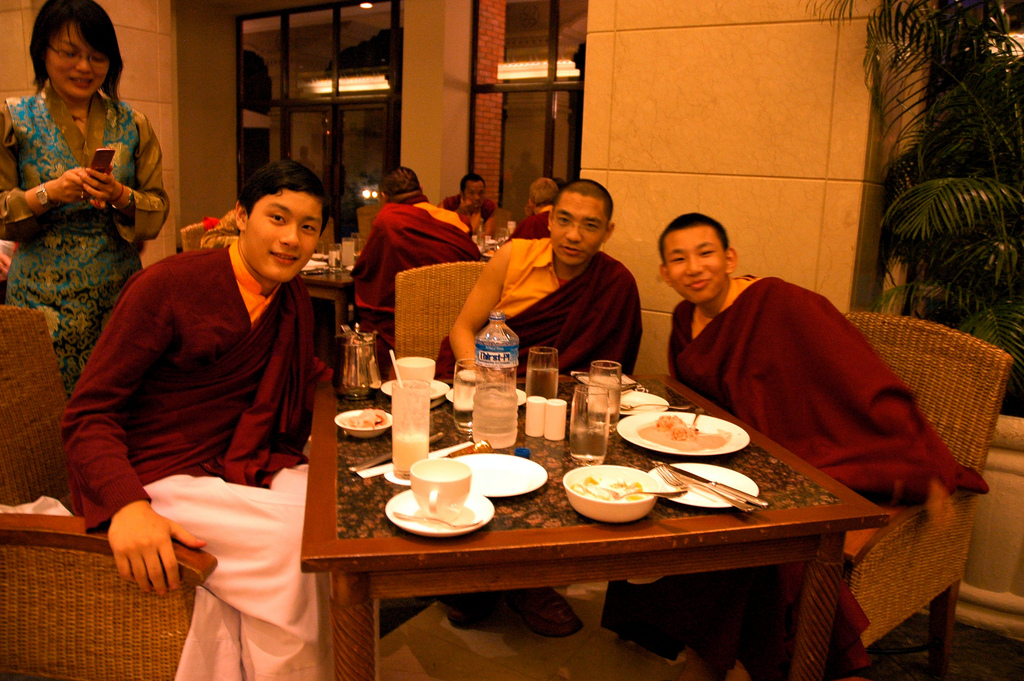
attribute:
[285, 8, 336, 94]
glass — clean, clear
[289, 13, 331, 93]
glass — paned, tinted, long, vertical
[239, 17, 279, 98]
glass — clear, clean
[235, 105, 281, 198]
glass — clean, clear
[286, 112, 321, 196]
glass — clean, clear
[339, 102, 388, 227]
glass — clear, clean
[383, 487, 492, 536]
dish — white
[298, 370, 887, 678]
table — wooden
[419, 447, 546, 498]
dish — white